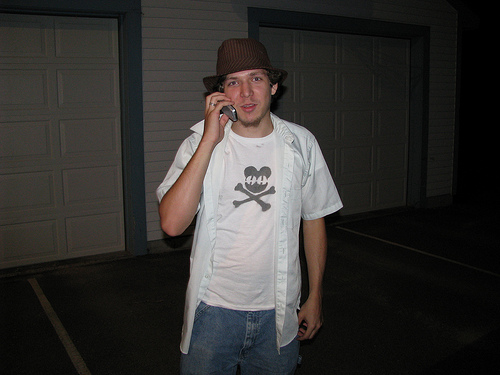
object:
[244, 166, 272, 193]
skull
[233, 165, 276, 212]
crossbone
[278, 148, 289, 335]
seam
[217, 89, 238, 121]
phone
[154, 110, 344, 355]
shirt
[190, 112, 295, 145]
collar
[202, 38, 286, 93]
hat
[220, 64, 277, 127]
head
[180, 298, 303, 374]
jeans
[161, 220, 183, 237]
elbow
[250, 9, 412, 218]
door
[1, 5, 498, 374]
garage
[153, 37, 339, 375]
man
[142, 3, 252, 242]
wall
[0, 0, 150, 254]
frame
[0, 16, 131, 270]
doors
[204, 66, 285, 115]
hair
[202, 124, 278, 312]
tshirt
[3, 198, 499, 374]
parking lot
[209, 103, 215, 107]
ring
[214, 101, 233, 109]
finger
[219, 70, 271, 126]
face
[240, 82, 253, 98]
nose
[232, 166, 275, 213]
design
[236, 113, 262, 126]
chin hair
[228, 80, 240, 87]
eye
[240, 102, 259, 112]
mouth